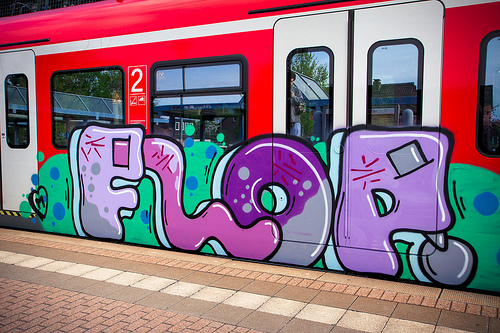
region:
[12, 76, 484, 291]
graffiti is on the train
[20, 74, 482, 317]
the graffiti os colorful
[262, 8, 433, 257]
the doors are white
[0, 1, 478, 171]
the train car is red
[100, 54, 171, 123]
number 2 is on the side of the train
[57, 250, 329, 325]
thew platform is made of bricks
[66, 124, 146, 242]
the letter "f" written as grafitti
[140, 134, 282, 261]
the letter "l" written as grafitti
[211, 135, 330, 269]
the letter "o" written as grafitti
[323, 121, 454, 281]
the letter "p" written as grafitti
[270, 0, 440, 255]
a door on a train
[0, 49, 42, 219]
a door on a train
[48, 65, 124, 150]
a window on a train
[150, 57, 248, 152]
a window on a train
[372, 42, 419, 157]
a window on a train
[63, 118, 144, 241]
graffiti on side of train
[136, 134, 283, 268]
graffiti on side of train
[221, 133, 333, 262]
graffiti on side of train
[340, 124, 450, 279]
graffiti on side of train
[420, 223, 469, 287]
graffiti on side of train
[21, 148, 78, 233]
graffiti on side of train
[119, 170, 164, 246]
graffiti on side of train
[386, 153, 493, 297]
graffiti on side of train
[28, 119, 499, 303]
graffiti on side of train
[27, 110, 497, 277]
graffiti on the side of the train car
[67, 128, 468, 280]
purple lettering in the graffiti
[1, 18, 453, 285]
white doors on the train car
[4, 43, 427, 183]
windows on the train doors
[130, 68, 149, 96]
white number on red background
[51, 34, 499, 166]
windows on the train car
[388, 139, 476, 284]
gray lettering in graffiti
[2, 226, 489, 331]
platform next to train car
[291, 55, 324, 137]
reflection on the door window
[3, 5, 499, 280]
red and white train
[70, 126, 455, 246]
purple and pink graffitti on train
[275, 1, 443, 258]
white doors of train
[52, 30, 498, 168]
black windows of train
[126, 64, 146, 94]
number 2 between two white doors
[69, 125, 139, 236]
f purple graffitti letter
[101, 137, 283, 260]
L pink graffitti letter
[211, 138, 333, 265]
purple and gray O graffitti letter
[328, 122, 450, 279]
purple graffiti P letter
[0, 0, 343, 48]
black thin lines on red train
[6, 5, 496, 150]
red paint on the train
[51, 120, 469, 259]
word painted on the train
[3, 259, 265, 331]
bricks are on the side walk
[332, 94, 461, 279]
the p is purple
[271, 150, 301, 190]
little red slashes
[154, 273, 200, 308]
the blocks are tan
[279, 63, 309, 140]
the reflection of a person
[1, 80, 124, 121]
the reflection of a roof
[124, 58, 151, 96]
the number 2 on train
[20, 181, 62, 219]
a heart on the train